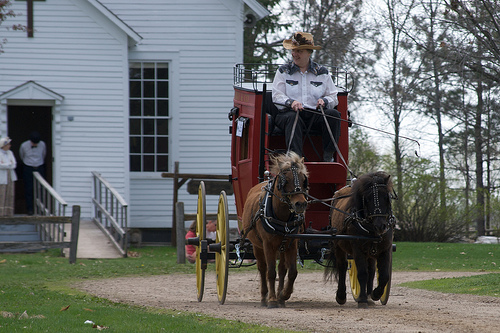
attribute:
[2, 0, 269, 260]
church — white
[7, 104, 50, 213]
doorway — open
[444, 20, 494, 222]
tree — tall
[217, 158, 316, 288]
horse — light brown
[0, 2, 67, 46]
cross — brown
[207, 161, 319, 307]
horses — red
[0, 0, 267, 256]
building — white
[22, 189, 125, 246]
ramp — wooden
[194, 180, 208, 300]
wheel — yellow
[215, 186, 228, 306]
wheel — yellow, wooden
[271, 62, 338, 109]
shirt — white, long-sleeve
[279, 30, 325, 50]
cowboy hat — tan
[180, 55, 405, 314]
wagon — red 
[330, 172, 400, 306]
horse — dark brown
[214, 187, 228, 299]
wheels — yellow, wooden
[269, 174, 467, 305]
horses — brown